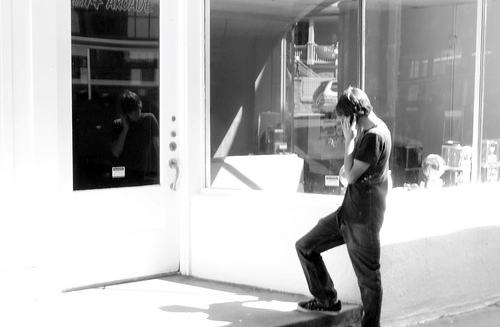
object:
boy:
[293, 88, 390, 319]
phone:
[348, 112, 363, 128]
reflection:
[106, 89, 157, 178]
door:
[47, 1, 196, 267]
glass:
[70, 0, 162, 193]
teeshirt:
[333, 124, 388, 226]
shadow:
[157, 294, 299, 325]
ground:
[0, 233, 499, 327]